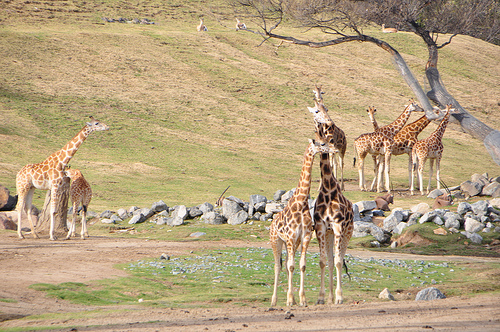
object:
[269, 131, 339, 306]
giraffes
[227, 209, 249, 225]
rocks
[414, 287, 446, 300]
rock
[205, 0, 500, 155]
tree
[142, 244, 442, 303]
grass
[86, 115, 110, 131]
head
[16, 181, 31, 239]
legs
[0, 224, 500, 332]
forefront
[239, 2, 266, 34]
branch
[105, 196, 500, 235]
wall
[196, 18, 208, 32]
animal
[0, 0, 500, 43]
distance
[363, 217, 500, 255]
moss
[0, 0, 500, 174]
hill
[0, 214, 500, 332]
ground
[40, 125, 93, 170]
neck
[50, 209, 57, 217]
knees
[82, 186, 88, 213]
tail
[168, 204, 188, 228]
stones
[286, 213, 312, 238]
chest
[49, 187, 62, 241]
leg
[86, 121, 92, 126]
ear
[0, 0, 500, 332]
wild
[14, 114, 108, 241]
giraffe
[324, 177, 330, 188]
spots